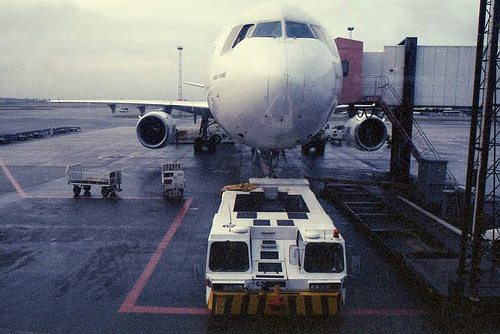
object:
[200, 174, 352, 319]
machine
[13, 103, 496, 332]
pavement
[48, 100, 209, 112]
wing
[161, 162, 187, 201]
carts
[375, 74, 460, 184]
stairs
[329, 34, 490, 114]
corridor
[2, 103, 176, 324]
runway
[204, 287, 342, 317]
paint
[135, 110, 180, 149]
engine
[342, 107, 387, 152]
engine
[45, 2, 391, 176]
airport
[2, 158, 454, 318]
line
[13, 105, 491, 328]
ground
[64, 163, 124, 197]
transporter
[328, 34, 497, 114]
transporter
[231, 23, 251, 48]
window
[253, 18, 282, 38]
window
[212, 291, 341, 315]
stripes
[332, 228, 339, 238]
light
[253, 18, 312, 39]
windshield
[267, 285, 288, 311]
fixture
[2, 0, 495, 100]
clouds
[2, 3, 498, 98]
sky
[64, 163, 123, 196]
cart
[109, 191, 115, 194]
tire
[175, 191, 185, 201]
tire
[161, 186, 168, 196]
tire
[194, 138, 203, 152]
tire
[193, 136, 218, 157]
vehicle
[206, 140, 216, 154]
tire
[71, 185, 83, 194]
tire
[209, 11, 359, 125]
nose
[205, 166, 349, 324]
refueling truck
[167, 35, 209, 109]
tower